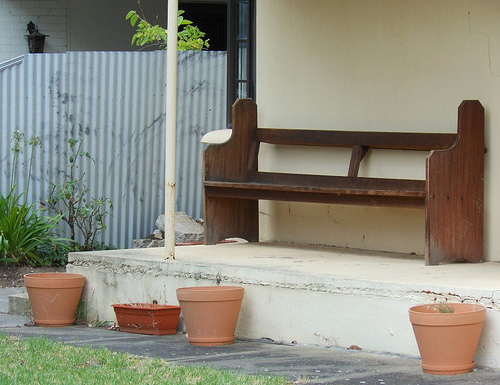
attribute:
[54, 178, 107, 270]
plant — small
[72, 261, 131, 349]
stoop — white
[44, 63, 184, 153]
fence — tall, white and plastic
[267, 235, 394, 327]
pad — concrete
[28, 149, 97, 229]
leaves —  long and green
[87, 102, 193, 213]
wall — metal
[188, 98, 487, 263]
wooden bench —  wooden,  with open back, wooden 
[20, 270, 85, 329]
terra cotta pot —  with no plant,  of terra cotta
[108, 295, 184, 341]
rectangular pot — round pot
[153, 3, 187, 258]
white pole — white and metal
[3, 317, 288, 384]
patch of grass — green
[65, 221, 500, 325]
cement pad — white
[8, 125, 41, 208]
thin trees — young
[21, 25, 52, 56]
planter pot — black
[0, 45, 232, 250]
metal fence — sheet metal wood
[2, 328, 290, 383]
green grass — green , small area, patch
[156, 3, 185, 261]
pole — cream colored , white metal wood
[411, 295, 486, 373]
orange pot — orange ceramic plant 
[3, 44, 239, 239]
corrugated wall — corrugated tin sheet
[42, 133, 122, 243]
green tree — growing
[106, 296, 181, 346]
dark pot — dark clay 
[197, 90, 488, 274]
wood bench — light stained wood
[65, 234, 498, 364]
porch — white concrete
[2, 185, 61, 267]
plant — short green 